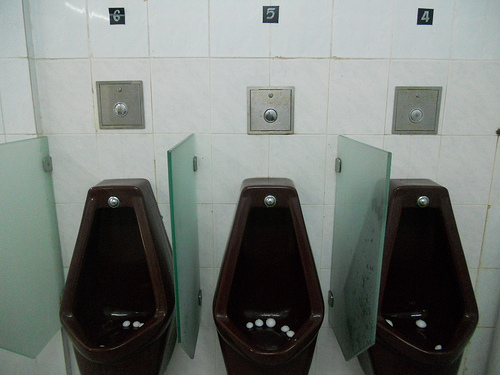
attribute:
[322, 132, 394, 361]
partition — glass, frosted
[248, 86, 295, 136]
fixture — silver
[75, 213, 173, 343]
urinals — wooden, identical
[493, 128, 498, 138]
spot — black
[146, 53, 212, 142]
tile — white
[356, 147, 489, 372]
urinal — brown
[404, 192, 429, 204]
knob — gray 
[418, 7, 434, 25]
number — four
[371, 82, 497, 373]
urinal — below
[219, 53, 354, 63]
grout — dirty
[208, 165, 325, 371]
urinal — brown 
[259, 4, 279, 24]
number — 5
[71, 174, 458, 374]
urinals — brown, three 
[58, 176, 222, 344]
urinal — brown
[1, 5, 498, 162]
wall — white 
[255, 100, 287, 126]
flusher — silver, above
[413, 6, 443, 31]
number — 4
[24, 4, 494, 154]
wall — bathroom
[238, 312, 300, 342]
tablets — cleaning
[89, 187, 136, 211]
knob — silver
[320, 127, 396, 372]
separator — glass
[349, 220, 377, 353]
splash — water